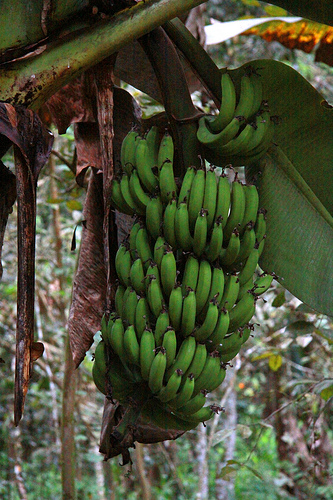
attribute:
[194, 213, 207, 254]
banana — green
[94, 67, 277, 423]
bananas — green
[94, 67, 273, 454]
bunch — long, large